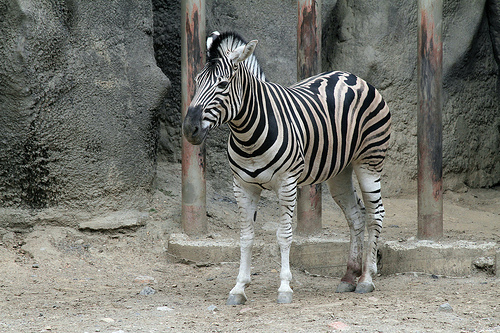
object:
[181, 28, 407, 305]
zebra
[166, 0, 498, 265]
bars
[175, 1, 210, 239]
bar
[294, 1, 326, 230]
bar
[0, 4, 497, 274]
wall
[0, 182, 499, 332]
floor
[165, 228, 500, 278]
base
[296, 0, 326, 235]
pole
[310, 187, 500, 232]
patch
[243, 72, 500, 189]
ground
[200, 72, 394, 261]
skin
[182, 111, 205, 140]
nose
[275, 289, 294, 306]
foot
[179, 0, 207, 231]
pillar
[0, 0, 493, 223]
rocks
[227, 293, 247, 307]
foot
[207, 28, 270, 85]
hair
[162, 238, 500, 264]
stone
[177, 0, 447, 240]
pillars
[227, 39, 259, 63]
ear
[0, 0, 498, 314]
scene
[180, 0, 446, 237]
posts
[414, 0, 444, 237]
post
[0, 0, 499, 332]
background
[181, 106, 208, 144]
snout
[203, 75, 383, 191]
stripes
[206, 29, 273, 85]
mane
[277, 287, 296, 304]
hoof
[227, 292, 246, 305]
hoof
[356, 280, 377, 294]
hoof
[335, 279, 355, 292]
hoof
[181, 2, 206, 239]
pole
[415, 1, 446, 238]
bar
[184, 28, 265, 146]
head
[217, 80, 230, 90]
eye